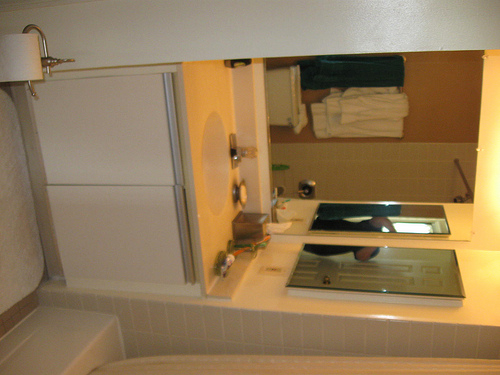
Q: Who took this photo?
A: A tourist.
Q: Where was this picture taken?
A: The bathroom.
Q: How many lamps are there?
A: One.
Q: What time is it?
A: Noon.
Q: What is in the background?
A: Towels.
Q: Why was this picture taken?
A: As a souvenir.